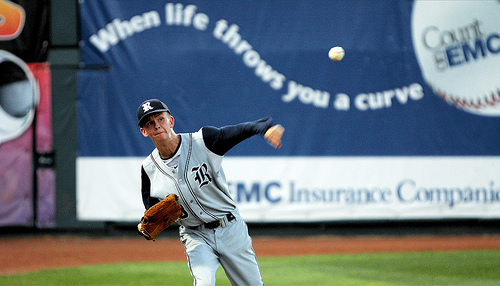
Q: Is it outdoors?
A: Yes, it is outdoors.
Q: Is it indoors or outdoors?
A: It is outdoors.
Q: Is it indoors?
A: No, it is outdoors.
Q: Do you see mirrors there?
A: No, there are no mirrors.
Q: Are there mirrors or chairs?
A: No, there are no mirrors or chairs.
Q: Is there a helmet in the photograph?
A: No, there are no helmets.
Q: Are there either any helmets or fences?
A: No, there are no helmets or fences.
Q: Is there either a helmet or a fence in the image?
A: No, there are no helmets or fences.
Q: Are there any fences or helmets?
A: No, there are no helmets or fences.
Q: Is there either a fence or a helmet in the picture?
A: No, there are no helmets or fences.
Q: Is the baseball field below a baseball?
A: Yes, the field is below a baseball.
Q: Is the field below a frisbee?
A: No, the field is below a baseball.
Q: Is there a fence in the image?
A: No, there are no fences.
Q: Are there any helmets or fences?
A: No, there are no fences or helmets.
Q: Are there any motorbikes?
A: No, there are no motorbikes.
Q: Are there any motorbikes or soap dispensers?
A: No, there are no motorbikes or soap dispensers.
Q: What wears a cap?
A: The pitcher wears a cap.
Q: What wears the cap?
A: The pitcher wears a cap.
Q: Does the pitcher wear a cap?
A: Yes, the pitcher wears a cap.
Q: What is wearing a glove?
A: The pitcher is wearing a glove.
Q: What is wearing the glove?
A: The pitcher is wearing a glove.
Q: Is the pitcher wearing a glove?
A: Yes, the pitcher is wearing a glove.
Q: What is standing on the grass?
A: The pitcher is standing on the grass.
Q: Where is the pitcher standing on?
A: The pitcher is standing on the grass.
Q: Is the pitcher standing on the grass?
A: Yes, the pitcher is standing on the grass.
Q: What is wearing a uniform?
A: The pitcher is wearing a uniform.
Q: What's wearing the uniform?
A: The pitcher is wearing a uniform.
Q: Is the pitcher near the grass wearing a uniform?
A: Yes, the pitcher is wearing a uniform.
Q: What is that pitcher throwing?
A: The pitcher is throwing the baseball.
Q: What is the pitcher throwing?
A: The pitcher is throwing the baseball.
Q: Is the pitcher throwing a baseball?
A: Yes, the pitcher is throwing a baseball.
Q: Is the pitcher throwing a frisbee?
A: No, the pitcher is throwing a baseball.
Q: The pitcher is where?
A: The pitcher is in the field.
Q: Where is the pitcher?
A: The pitcher is in the field.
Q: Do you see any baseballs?
A: Yes, there is a baseball.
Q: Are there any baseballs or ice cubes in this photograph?
A: Yes, there is a baseball.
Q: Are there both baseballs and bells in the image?
A: No, there is a baseball but no bells.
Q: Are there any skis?
A: No, there are no skis.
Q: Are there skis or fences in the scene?
A: No, there are no skis or fences.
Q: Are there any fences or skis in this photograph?
A: No, there are no skis or fences.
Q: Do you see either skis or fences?
A: No, there are no skis or fences.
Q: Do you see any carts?
A: No, there are no carts.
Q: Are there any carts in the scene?
A: No, there are no carts.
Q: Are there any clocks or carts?
A: No, there are no carts or clocks.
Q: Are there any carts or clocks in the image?
A: No, there are no carts or clocks.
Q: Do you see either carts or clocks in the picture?
A: No, there are no carts or clocks.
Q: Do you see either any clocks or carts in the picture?
A: No, there are no carts or clocks.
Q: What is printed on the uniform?
A: The letter is printed on the uniform.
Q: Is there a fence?
A: No, there are no fences.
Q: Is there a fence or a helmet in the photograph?
A: No, there are no fences or helmets.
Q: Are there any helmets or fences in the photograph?
A: No, there are no fences or helmets.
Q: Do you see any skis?
A: No, there are no skis.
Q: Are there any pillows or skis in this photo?
A: No, there are no skis or pillows.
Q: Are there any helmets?
A: No, there are no helmets.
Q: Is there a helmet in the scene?
A: No, there are no helmets.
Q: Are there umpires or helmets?
A: No, there are no helmets or umpires.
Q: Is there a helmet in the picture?
A: No, there are no helmets.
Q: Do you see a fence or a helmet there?
A: No, there are no helmets or fences.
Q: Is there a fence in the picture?
A: No, there are no fences.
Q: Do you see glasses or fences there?
A: No, there are no fences or glasses.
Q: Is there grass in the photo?
A: Yes, there is grass.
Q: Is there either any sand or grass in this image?
A: Yes, there is grass.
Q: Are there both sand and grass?
A: No, there is grass but no sand.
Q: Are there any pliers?
A: No, there are no pliers.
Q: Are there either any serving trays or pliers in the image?
A: No, there are no pliers or serving trays.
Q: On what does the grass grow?
A: The grass grows on the field.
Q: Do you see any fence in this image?
A: No, there are no fences.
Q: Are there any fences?
A: No, there are no fences.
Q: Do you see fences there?
A: No, there are no fences.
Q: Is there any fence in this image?
A: No, there are no fences.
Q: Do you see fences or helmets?
A: No, there are no fences or helmets.